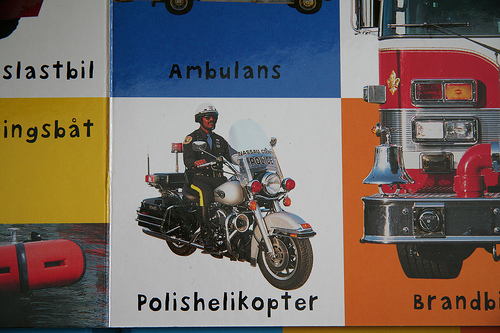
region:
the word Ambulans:
[167, 62, 283, 84]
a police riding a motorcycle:
[136, 108, 318, 288]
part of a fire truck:
[375, 18, 497, 235]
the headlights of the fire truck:
[409, 75, 491, 141]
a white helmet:
[193, 103, 216, 120]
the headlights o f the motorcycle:
[253, 173, 296, 210]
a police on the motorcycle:
[137, 100, 314, 285]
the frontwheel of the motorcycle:
[258, 228, 314, 289]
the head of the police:
[198, 107, 219, 129]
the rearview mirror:
[268, 135, 279, 147]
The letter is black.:
[131, 288, 148, 316]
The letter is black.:
[147, 293, 162, 313]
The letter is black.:
[161, 287, 173, 313]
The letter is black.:
[171, 290, 180, 314]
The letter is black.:
[179, 290, 192, 313]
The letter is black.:
[191, 288, 207, 315]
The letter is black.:
[207, 295, 222, 315]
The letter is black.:
[218, 287, 229, 317]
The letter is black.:
[227, 287, 237, 312]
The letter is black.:
[235, 285, 249, 313]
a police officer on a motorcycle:
[137, 106, 315, 288]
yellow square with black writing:
[1, 96, 109, 219]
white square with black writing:
[2, 8, 109, 95]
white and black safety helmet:
[193, 103, 217, 129]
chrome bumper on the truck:
[360, 190, 497, 243]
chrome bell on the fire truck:
[365, 144, 412, 186]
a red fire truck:
[362, 2, 499, 277]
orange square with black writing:
[343, 100, 495, 321]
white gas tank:
[211, 179, 243, 206]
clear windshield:
[229, 118, 279, 188]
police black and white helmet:
[191, 97, 220, 131]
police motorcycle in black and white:
[132, 125, 332, 297]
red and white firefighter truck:
[350, 3, 498, 282]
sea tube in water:
[6, 228, 91, 304]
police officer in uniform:
[177, 100, 256, 260]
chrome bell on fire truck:
[361, 123, 417, 196]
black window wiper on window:
[377, 15, 474, 40]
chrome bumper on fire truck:
[347, 185, 498, 263]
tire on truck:
[385, 228, 465, 291]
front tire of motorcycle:
[244, 205, 325, 290]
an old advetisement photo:
[13, 12, 484, 297]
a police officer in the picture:
[143, 110, 337, 278]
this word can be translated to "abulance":
[136, 39, 309, 92]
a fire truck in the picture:
[347, 9, 499, 267]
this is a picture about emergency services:
[15, 20, 464, 296]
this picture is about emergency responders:
[10, 15, 445, 295]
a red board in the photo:
[7, 227, 95, 295]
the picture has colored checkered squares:
[34, 25, 411, 290]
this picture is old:
[19, 13, 458, 318]